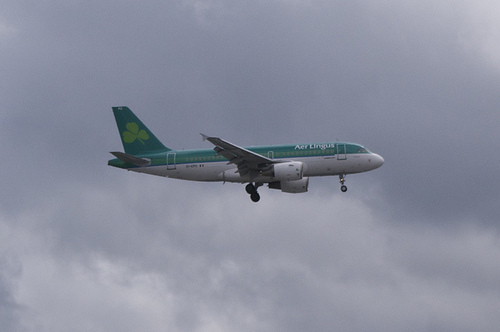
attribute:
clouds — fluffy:
[35, 212, 165, 329]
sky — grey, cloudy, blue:
[69, 16, 383, 87]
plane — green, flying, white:
[91, 78, 396, 211]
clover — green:
[119, 115, 152, 149]